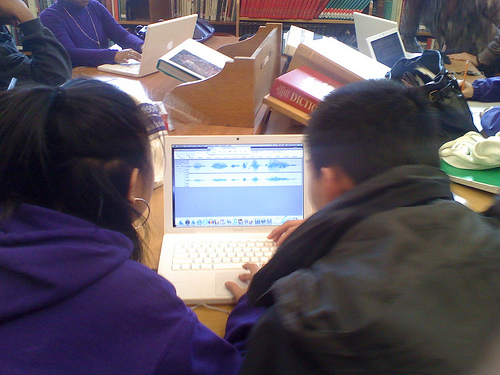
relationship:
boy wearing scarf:
[233, 76, 499, 371] [241, 160, 459, 308]